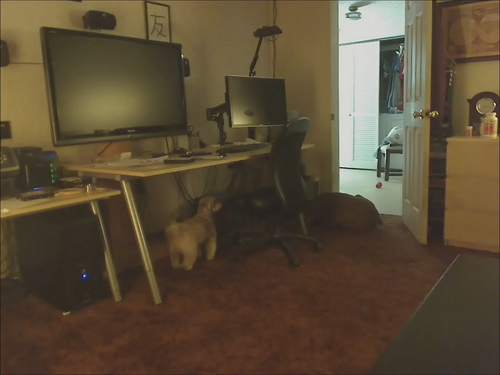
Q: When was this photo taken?
A: Daytime.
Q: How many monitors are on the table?
A: Two.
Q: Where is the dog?
A: Under the table.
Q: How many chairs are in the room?
A: One.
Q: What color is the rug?
A: Red.